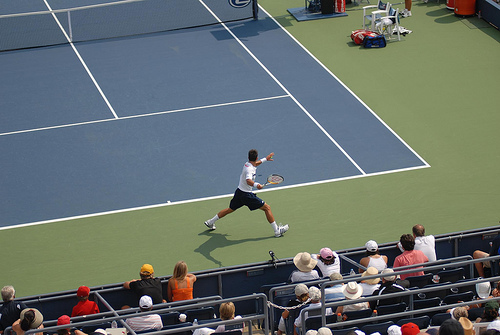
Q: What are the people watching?
A: A tennis match.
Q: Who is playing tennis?
A: The man.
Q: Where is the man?
A: On the tennis court.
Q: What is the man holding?
A: A racket.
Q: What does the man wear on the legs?
A: Shorts.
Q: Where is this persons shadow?
A: Behind the person.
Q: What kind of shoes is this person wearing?
A: Tennis shoes.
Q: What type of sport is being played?
A: Tennis.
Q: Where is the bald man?
A: On the far right.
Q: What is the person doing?
A: Getting ready to hit the ball.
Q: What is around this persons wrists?
A: Arm bands.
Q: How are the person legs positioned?
A: Apart.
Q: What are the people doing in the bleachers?
A: Watching the game.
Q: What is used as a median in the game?
A: A net.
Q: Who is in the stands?
A: Spectators.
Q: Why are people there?
A: To watch the match.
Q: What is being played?
A: Tennis.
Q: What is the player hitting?
A: A tennis ball.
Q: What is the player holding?
A: A racket.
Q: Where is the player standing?
A: On the court.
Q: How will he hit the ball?
A: With the tennis racket.